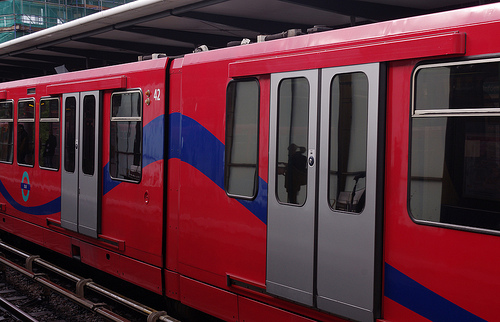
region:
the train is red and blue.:
[1, 59, 498, 319]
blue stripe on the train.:
[160, 98, 476, 318]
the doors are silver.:
[257, 49, 391, 319]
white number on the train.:
[148, 82, 165, 102]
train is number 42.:
[147, 83, 164, 105]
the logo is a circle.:
[15, 165, 32, 202]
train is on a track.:
[1, 234, 186, 319]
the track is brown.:
[2, 234, 184, 317]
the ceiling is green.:
[0, 3, 90, 49]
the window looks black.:
[401, 60, 498, 232]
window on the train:
[111, 95, 146, 176]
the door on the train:
[270, 70, 365, 300]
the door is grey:
[270, 71, 370, 301]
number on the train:
[145, 81, 160, 101]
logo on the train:
[12, 170, 37, 195]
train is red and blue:
[165, 51, 215, 136]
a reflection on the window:
[328, 163, 361, 208]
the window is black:
[410, 70, 498, 220]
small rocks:
[28, 288, 49, 304]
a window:
[226, 81, 257, 192]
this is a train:
[53, 119, 342, 308]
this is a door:
[245, 19, 337, 314]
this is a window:
[290, 155, 360, 217]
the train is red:
[88, 91, 230, 233]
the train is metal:
[119, 63, 271, 225]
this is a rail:
[32, 251, 41, 300]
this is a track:
[25, 299, 30, 306]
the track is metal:
[18, 302, 25, 316]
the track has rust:
[2, 294, 42, 312]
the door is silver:
[244, 158, 334, 280]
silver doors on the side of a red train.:
[249, 42, 389, 319]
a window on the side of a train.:
[220, 69, 269, 209]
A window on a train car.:
[404, 58, 499, 242]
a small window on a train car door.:
[323, 71, 371, 216]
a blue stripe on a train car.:
[163, 113, 481, 319]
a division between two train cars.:
[156, 50, 177, 300]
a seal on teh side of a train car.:
[9, 171, 39, 205]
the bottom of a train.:
[1, 257, 195, 319]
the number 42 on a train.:
[140, 80, 165, 110]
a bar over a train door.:
[224, 28, 481, 80]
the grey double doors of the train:
[266, 54, 383, 320]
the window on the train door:
[325, 75, 366, 210]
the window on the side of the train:
[400, 62, 496, 227]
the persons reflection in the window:
[273, 138, 313, 198]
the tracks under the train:
[1, 231, 123, 320]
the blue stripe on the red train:
[1, 170, 60, 234]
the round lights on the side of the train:
[140, 83, 155, 122]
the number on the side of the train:
[153, 84, 163, 104]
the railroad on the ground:
[1, 285, 35, 319]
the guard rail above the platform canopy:
[1, 12, 51, 28]